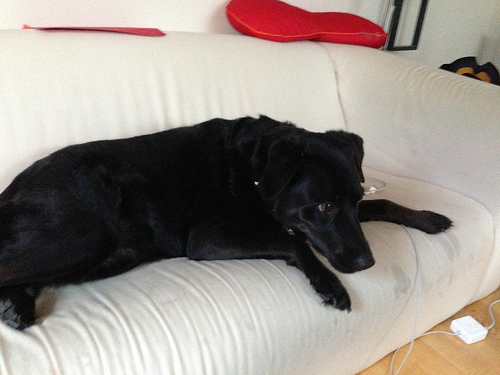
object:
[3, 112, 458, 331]
dog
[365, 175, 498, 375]
charger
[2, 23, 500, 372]
couch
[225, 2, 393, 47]
pillow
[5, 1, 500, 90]
wall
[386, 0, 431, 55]
frame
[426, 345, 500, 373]
floor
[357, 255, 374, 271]
nose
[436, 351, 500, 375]
wood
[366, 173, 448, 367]
wire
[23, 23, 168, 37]
item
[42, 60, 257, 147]
row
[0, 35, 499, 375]
fabric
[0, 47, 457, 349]
row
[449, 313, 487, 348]
box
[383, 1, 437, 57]
mirror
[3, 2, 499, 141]
background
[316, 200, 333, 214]
eye